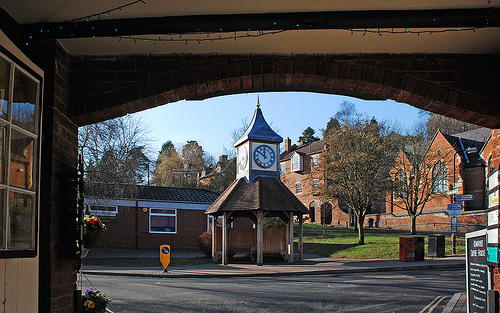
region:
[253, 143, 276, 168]
a clock face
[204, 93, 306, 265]
a gazebo with clock tower on top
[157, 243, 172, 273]
a small orange sign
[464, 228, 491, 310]
a black and white informational sign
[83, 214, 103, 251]
a hanging bunch of flowers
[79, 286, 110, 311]
a hanging basket with colorful flowers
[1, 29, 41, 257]
a mulit-paned window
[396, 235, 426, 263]
a brown box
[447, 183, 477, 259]
a group of street signs on one pole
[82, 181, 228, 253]
a one story building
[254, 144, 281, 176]
clock on top of mini tower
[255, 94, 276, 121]
spire on top of clock tower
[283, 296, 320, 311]
black asphalt road in center of town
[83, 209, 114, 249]
red white and green flowers in baskets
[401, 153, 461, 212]
bare tree on right of photo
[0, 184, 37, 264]
window pane with white sills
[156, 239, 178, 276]
yellow sign on sidewalk with blue arrow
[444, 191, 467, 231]
blue and white street signs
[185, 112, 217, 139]
light blue patch of sky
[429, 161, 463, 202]
decorative rounded top window on brick building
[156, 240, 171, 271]
yellow sign on the sidewalk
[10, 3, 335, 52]
blue and green lights hanging across the roof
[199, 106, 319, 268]
a gazebo with a clock tower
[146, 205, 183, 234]
window in a red brick building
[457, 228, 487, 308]
black and white sign on the sidewalk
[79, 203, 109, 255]
flowers in a hanging pot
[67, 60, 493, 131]
brick archway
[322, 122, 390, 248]
tree in the grass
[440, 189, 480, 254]
street signs in the grass by the sidewalk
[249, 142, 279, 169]
clock above the gazebo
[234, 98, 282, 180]
a multi faced clock tower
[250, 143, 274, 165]
a white clock face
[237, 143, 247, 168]
a white clock face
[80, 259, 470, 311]
a paved city street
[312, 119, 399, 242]
a large green tree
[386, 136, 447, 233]
a bare leaf tree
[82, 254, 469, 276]
a paved sidewalk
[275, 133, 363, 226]
a large building in distance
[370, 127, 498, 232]
a large building in distance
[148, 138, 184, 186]
a large green tree in distance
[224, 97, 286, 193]
a clock tower that is not real tall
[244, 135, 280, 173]
the clock reads 10 til 12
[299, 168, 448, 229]
these buildings are made of brick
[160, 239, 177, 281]
an orange sign is in front by the curb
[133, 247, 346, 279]
the sidewalk appears made out of brick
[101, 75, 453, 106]
this building is made of brick as well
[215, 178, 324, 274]
the lower part of the tower appears to be a gazebo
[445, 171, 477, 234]
the street signs point in various directions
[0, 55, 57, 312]
this door glass is divided into numerous panes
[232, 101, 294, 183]
the clock tower is white & blue